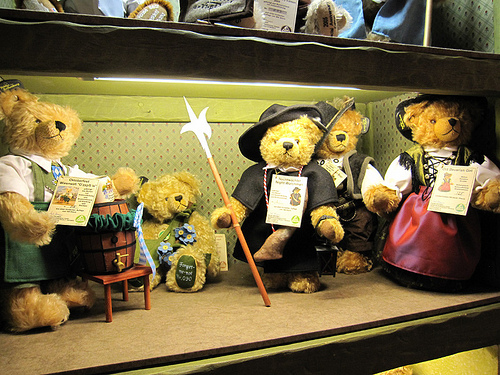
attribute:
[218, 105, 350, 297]
bear — Teddy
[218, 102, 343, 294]
teddy bear — brown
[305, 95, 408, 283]
teddybear — brown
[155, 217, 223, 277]
tie — floral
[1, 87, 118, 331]
tedbear — Teddy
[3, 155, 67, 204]
shirt — white, green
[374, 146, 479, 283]
dress — pink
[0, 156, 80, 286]
jumper — green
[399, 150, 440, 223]
costume — traditional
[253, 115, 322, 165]
head — Teddybear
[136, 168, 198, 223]
head — Teddybear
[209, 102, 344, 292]
tedbear — Teddy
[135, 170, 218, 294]
tedbear — Teddy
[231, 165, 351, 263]
jacket — black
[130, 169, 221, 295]
bear — ted, Teddy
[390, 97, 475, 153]
head — Teddybear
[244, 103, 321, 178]
head — Teddybear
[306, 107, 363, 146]
head — Teddybear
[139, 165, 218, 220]
head — Teddybear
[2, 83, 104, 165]
head — Teddybear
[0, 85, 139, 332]
bear — brown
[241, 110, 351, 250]
head — Teddybear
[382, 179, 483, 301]
skirt — red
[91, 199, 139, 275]
keg — toy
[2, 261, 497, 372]
table — wooden